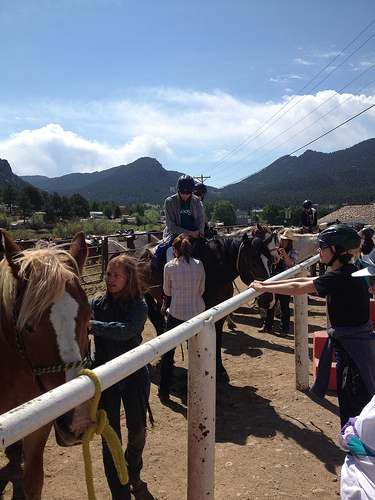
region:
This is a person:
[311, 213, 374, 450]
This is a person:
[80, 251, 161, 495]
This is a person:
[151, 229, 234, 444]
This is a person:
[162, 166, 220, 248]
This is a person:
[264, 224, 306, 346]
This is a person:
[289, 193, 322, 241]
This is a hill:
[122, 146, 167, 186]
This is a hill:
[164, 158, 187, 184]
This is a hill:
[50, 152, 99, 191]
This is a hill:
[246, 127, 327, 205]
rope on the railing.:
[104, 433, 129, 480]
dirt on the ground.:
[236, 461, 266, 481]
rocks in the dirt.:
[271, 490, 289, 498]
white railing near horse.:
[182, 301, 228, 332]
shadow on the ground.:
[229, 399, 260, 423]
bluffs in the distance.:
[118, 165, 151, 196]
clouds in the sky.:
[202, 98, 237, 121]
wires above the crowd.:
[258, 113, 290, 145]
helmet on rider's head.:
[173, 174, 193, 191]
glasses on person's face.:
[311, 245, 327, 254]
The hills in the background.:
[4, 139, 371, 201]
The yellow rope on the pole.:
[73, 366, 134, 498]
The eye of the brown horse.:
[23, 314, 40, 333]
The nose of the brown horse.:
[61, 418, 97, 438]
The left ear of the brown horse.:
[0, 224, 30, 279]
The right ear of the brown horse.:
[68, 229, 90, 268]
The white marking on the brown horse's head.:
[49, 290, 85, 380]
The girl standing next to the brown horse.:
[78, 254, 151, 499]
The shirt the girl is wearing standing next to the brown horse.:
[85, 288, 148, 349]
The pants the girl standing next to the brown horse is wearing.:
[92, 381, 147, 486]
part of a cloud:
[142, 134, 166, 147]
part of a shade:
[244, 427, 262, 448]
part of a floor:
[291, 446, 309, 459]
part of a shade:
[237, 408, 283, 477]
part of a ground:
[250, 458, 278, 485]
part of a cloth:
[306, 360, 343, 393]